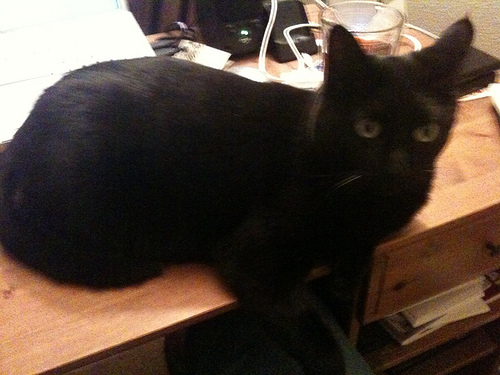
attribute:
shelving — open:
[353, 272, 499, 371]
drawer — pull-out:
[358, 199, 499, 329]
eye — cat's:
[346, 99, 393, 144]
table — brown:
[31, 279, 95, 365]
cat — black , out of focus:
[10, 17, 474, 373]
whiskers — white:
[321, 171, 363, 193]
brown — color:
[14, 255, 300, 369]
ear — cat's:
[402, 22, 485, 85]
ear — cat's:
[300, 15, 407, 100]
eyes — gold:
[352, 119, 442, 150]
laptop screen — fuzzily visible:
[0, 5, 161, 145]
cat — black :
[2, 15, 478, 337]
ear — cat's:
[405, 11, 478, 91]